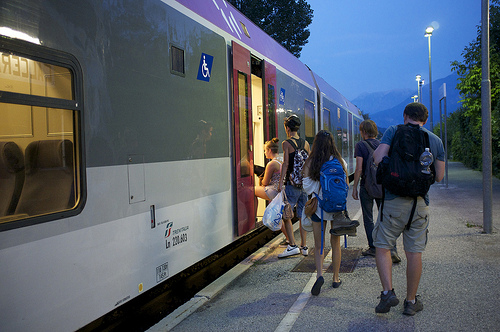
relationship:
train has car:
[1, 0, 367, 331] [0, 0, 318, 331]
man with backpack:
[373, 102, 445, 316] [375, 124, 436, 198]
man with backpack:
[353, 121, 400, 264] [363, 138, 386, 199]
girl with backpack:
[300, 130, 358, 296] [318, 157, 349, 214]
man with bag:
[278, 114, 310, 257] [261, 191, 285, 234]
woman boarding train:
[253, 138, 285, 221] [1, 0, 367, 331]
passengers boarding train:
[255, 103, 446, 316] [1, 0, 367, 331]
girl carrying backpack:
[300, 130, 358, 296] [318, 157, 349, 214]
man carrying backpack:
[373, 102, 445, 316] [375, 124, 436, 198]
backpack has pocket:
[375, 124, 436, 198] [421, 171, 432, 196]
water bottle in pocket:
[420, 147, 433, 173] [421, 171, 432, 196]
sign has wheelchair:
[197, 52, 214, 82] [201, 53, 211, 77]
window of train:
[1, 34, 88, 235] [1, 0, 367, 331]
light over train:
[424, 23, 436, 38] [1, 0, 367, 331]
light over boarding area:
[424, 23, 436, 38] [143, 147, 499, 332]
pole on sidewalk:
[481, 2, 493, 233] [140, 161, 499, 332]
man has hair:
[373, 102, 445, 316] [402, 101, 428, 123]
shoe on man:
[373, 288, 400, 313] [373, 102, 445, 316]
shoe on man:
[403, 298, 424, 316] [373, 102, 445, 316]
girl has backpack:
[300, 130, 358, 296] [318, 157, 349, 214]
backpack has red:
[375, 124, 436, 198] [389, 170, 400, 180]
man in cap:
[278, 114, 310, 257] [285, 114, 301, 128]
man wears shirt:
[353, 121, 400, 264] [353, 138, 381, 188]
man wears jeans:
[353, 121, 400, 264] [360, 185, 398, 254]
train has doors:
[1, 0, 367, 331] [232, 38, 280, 237]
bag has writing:
[261, 191, 285, 234] [271, 203, 285, 230]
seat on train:
[13, 140, 74, 215] [1, 0, 367, 331]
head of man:
[360, 119, 380, 140] [353, 121, 400, 264]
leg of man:
[359, 177, 375, 259] [353, 121, 400, 264]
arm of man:
[352, 144, 363, 201] [353, 121, 400, 264]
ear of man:
[402, 112, 408, 121] [373, 102, 445, 316]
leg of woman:
[255, 185, 277, 218] [253, 138, 285, 221]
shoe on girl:
[310, 276, 324, 296] [300, 130, 358, 296]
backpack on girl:
[318, 157, 349, 214] [300, 130, 358, 296]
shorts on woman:
[265, 185, 281, 199] [253, 138, 285, 221]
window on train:
[1, 34, 88, 235] [1, 0, 367, 331]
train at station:
[1, 0, 367, 331] [127, 0, 499, 331]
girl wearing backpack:
[300, 130, 358, 296] [318, 157, 349, 214]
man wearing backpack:
[373, 102, 445, 316] [375, 124, 436, 198]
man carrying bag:
[278, 114, 310, 257] [261, 191, 285, 234]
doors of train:
[232, 38, 280, 237] [1, 0, 367, 331]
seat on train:
[1, 142, 23, 216] [1, 0, 367, 331]